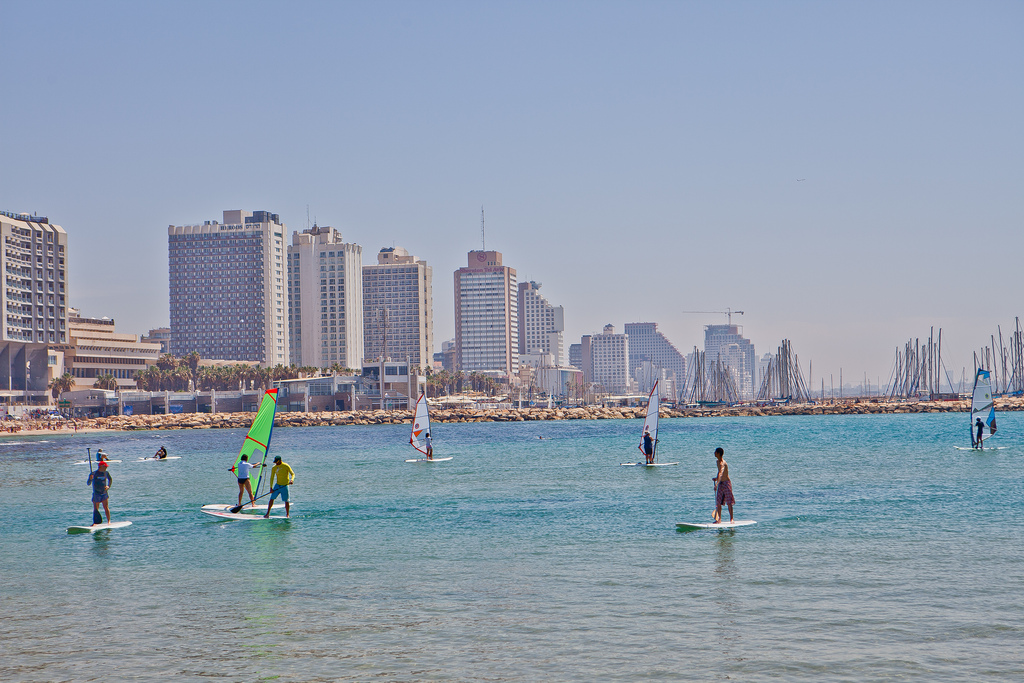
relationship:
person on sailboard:
[223, 454, 277, 524] [216, 382, 277, 506]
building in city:
[616, 311, 656, 385] [8, 205, 1022, 426]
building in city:
[624, 322, 687, 400] [8, 198, 987, 445]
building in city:
[704, 322, 747, 396] [8, 198, 987, 445]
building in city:
[72, 308, 164, 369] [8, 198, 987, 445]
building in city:
[170, 215, 294, 372] [4, 214, 1014, 413]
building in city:
[276, 223, 360, 366] [4, 214, 1014, 413]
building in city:
[350, 253, 427, 377] [4, 214, 1014, 413]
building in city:
[448, 242, 528, 389] [4, 214, 1014, 413]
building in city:
[511, 281, 566, 376] [4, 214, 1014, 413]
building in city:
[592, 324, 632, 381] [4, 214, 1014, 413]